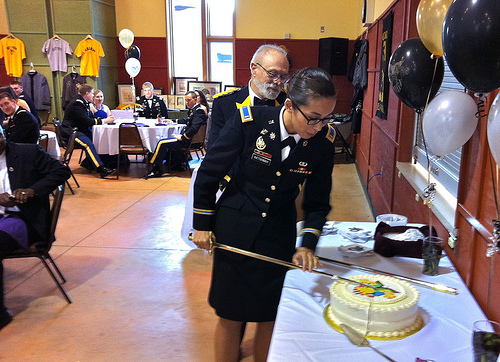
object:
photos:
[118, 84, 136, 105]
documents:
[120, 101, 134, 110]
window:
[169, 1, 236, 80]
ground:
[428, 134, 466, 175]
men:
[142, 91, 206, 178]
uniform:
[191, 106, 338, 325]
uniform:
[55, 92, 104, 170]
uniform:
[149, 103, 207, 166]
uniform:
[0, 107, 40, 146]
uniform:
[0, 139, 72, 311]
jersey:
[0, 33, 26, 79]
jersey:
[39, 32, 74, 74]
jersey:
[74, 33, 105, 78]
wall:
[115, 1, 164, 97]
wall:
[231, 2, 363, 130]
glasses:
[288, 96, 336, 127]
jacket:
[186, 104, 337, 252]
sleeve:
[193, 100, 245, 232]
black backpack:
[352, 40, 367, 90]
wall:
[350, 0, 499, 330]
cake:
[323, 270, 424, 337]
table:
[265, 220, 497, 362]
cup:
[418, 236, 447, 275]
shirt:
[349, 43, 369, 89]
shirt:
[60, 71, 86, 108]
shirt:
[346, 86, 366, 135]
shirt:
[17, 69, 53, 111]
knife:
[186, 229, 386, 294]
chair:
[0, 179, 75, 305]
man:
[205, 43, 291, 151]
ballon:
[416, 0, 453, 53]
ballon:
[441, 0, 498, 94]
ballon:
[421, 86, 479, 160]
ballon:
[388, 40, 445, 112]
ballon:
[114, 28, 138, 49]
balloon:
[487, 88, 500, 167]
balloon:
[122, 53, 142, 80]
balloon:
[123, 57, 141, 79]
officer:
[190, 65, 341, 360]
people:
[53, 85, 119, 178]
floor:
[0, 138, 376, 362]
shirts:
[347, 39, 363, 84]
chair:
[117, 123, 149, 181]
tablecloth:
[93, 119, 182, 157]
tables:
[0, 129, 58, 161]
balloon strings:
[420, 154, 436, 240]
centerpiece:
[395, 10, 498, 285]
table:
[87, 113, 187, 167]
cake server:
[337, 320, 397, 360]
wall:
[5, 0, 167, 128]